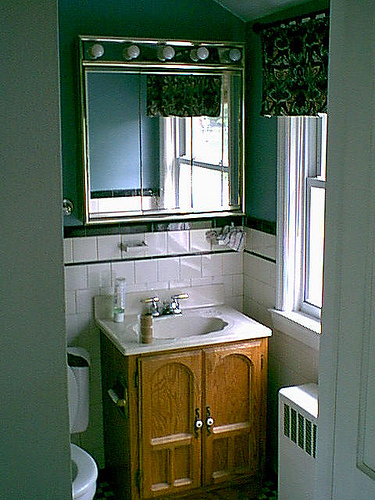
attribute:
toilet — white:
[62, 345, 98, 499]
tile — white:
[127, 248, 201, 285]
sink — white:
[95, 300, 279, 359]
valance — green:
[257, 5, 333, 124]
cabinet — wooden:
[127, 338, 271, 499]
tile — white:
[155, 252, 228, 280]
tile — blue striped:
[80, 250, 223, 268]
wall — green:
[5, 17, 57, 423]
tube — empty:
[100, 385, 134, 414]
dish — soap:
[113, 239, 155, 259]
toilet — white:
[62, 336, 112, 498]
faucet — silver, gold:
[143, 289, 188, 318]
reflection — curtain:
[139, 78, 222, 122]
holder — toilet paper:
[102, 384, 127, 416]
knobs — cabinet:
[190, 405, 212, 434]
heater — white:
[272, 376, 330, 498]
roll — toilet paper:
[137, 308, 155, 344]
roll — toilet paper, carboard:
[138, 310, 155, 342]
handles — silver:
[135, 288, 198, 320]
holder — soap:
[116, 235, 161, 264]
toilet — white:
[68, 338, 100, 496]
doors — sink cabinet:
[138, 347, 261, 499]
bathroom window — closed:
[284, 115, 322, 327]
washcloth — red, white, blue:
[200, 220, 249, 255]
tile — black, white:
[70, 220, 277, 267]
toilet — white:
[64, 338, 121, 497]